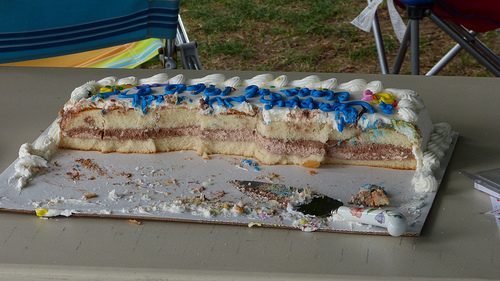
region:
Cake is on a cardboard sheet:
[0, 68, 467, 241]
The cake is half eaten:
[58, 63, 427, 220]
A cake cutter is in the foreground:
[223, 170, 425, 249]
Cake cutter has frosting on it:
[233, 170, 319, 217]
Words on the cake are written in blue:
[102, 76, 373, 129]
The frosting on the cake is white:
[73, 69, 418, 131]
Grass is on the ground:
[192, 1, 348, 54]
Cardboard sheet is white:
[6, 147, 435, 231]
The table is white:
[6, 66, 495, 278]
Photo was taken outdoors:
[1, 2, 498, 276]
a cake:
[233, 89, 305, 171]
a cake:
[303, 66, 370, 159]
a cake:
[289, 101, 347, 175]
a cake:
[313, 51, 334, 111]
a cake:
[182, 31, 295, 213]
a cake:
[230, 53, 325, 208]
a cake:
[256, 110, 318, 185]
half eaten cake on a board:
[4, 63, 469, 253]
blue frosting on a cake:
[97, 86, 397, 128]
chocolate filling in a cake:
[59, 121, 413, 167]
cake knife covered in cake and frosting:
[225, 172, 411, 240]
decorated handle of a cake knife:
[335, 199, 407, 237]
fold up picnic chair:
[357, 1, 498, 79]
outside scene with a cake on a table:
[2, 0, 496, 279]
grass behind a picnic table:
[155, 2, 498, 82]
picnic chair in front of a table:
[4, 3, 199, 78]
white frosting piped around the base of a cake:
[408, 114, 458, 197]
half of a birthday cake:
[0, 70, 464, 239]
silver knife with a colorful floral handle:
[225, 172, 417, 238]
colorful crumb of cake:
[342, 179, 391, 207]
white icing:
[14, 133, 54, 187]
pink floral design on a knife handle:
[347, 205, 376, 219]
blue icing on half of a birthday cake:
[56, 73, 428, 169]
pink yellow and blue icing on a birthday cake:
[361, 88, 397, 113]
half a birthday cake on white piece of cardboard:
[0, 71, 462, 244]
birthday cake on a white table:
[0, 71, 464, 238]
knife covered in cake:
[220, 175, 406, 234]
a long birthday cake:
[56, 65, 442, 170]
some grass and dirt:
[195, 5, 342, 65]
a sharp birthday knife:
[225, 176, 430, 242]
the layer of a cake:
[90, 116, 336, 163]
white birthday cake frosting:
[15, 130, 50, 180]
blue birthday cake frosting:
[267, 80, 347, 105]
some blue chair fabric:
[0, 1, 170, 51]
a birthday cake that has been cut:
[62, 70, 437, 186]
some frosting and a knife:
[54, 153, 429, 249]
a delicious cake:
[62, 68, 424, 178]